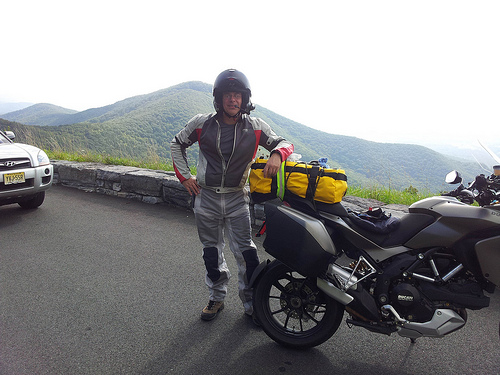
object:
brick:
[48, 160, 409, 251]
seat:
[315, 196, 443, 249]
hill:
[0, 81, 500, 197]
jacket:
[170, 112, 295, 193]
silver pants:
[192, 185, 267, 316]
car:
[0, 128, 53, 209]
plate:
[2, 172, 25, 185]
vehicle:
[242, 139, 499, 351]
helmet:
[212, 68, 256, 114]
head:
[212, 69, 256, 117]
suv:
[0, 128, 53, 213]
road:
[0, 156, 499, 374]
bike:
[241, 153, 500, 374]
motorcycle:
[246, 149, 500, 350]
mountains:
[0, 81, 497, 206]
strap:
[250, 162, 348, 182]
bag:
[248, 153, 347, 206]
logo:
[4, 161, 17, 168]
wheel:
[250, 257, 345, 348]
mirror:
[445, 170, 463, 184]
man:
[170, 69, 294, 326]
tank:
[261, 199, 333, 276]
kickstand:
[397, 334, 417, 369]